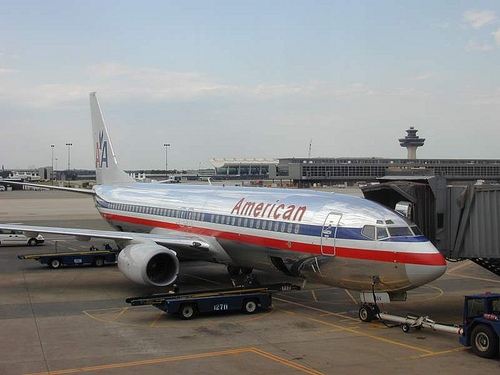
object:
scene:
[2, 4, 499, 372]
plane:
[0, 85, 456, 316]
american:
[223, 191, 316, 226]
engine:
[106, 239, 188, 294]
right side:
[5, 211, 222, 305]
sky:
[3, 0, 499, 158]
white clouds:
[13, 59, 474, 126]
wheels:
[354, 299, 381, 327]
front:
[326, 196, 458, 334]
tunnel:
[368, 174, 499, 264]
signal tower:
[393, 120, 432, 164]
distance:
[288, 107, 495, 152]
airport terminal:
[195, 122, 497, 184]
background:
[0, 108, 499, 180]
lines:
[17, 292, 449, 373]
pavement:
[0, 240, 499, 373]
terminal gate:
[174, 147, 499, 200]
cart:
[121, 273, 302, 319]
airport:
[0, 89, 499, 371]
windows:
[360, 214, 430, 243]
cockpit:
[354, 215, 441, 246]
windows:
[106, 198, 303, 234]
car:
[0, 227, 49, 247]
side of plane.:
[100, 190, 345, 250]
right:
[397, 52, 493, 374]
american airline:
[84, 126, 121, 173]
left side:
[78, 194, 343, 299]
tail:
[82, 88, 145, 191]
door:
[312, 203, 347, 261]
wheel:
[27, 236, 40, 250]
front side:
[23, 234, 47, 246]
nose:
[403, 233, 452, 290]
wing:
[0, 219, 211, 251]